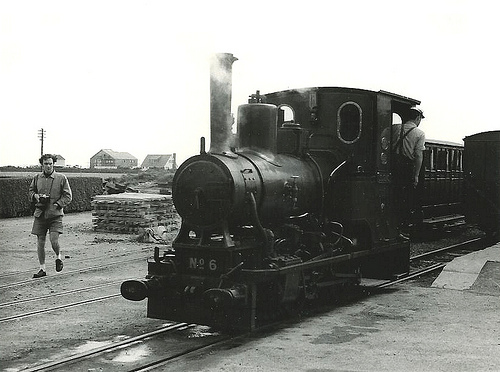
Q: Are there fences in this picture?
A: No, there are no fences.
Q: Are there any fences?
A: No, there are no fences.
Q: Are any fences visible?
A: No, there are no fences.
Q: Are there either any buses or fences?
A: No, there are no fences or buses.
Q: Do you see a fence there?
A: No, there are no fences.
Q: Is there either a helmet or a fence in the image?
A: No, there are no fences or helmets.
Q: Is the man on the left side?
A: Yes, the man is on the left of the image.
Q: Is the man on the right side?
A: No, the man is on the left of the image.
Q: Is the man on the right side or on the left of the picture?
A: The man is on the left of the image.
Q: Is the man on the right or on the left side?
A: The man is on the left of the image.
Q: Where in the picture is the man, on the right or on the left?
A: The man is on the left of the image.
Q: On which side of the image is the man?
A: The man is on the left of the image.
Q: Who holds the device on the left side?
A: The man holds the camera.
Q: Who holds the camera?
A: The man holds the camera.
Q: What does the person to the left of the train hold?
A: The man holds the camera.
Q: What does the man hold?
A: The man holds the camera.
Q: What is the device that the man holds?
A: The device is a camera.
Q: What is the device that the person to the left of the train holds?
A: The device is a camera.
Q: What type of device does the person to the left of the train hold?
A: The man holds the camera.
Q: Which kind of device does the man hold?
A: The man holds the camera.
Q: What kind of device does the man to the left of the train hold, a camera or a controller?
A: The man holds a camera.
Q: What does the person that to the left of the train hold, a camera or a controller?
A: The man holds a camera.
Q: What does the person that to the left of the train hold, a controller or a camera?
A: The man holds a camera.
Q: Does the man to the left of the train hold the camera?
A: Yes, the man holds the camera.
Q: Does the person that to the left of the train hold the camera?
A: Yes, the man holds the camera.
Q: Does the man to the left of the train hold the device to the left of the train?
A: Yes, the man holds the camera.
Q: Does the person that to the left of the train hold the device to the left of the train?
A: Yes, the man holds the camera.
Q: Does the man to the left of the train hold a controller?
A: No, the man holds the camera.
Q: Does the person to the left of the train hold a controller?
A: No, the man holds the camera.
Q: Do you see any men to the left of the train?
A: Yes, there is a man to the left of the train.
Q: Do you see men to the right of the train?
A: No, the man is to the left of the train.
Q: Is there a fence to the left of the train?
A: No, there is a man to the left of the train.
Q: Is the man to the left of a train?
A: Yes, the man is to the left of a train.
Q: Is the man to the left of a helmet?
A: No, the man is to the left of a train.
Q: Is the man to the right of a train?
A: No, the man is to the left of a train.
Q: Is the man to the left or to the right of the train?
A: The man is to the left of the train.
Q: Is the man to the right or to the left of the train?
A: The man is to the left of the train.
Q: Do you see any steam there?
A: Yes, there is steam.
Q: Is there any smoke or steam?
A: Yes, there is steam.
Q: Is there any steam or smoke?
A: Yes, there is steam.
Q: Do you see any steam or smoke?
A: Yes, there is steam.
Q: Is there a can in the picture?
A: No, there are no cans.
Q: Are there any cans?
A: No, there are no cans.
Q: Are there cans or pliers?
A: No, there are no cans or pliers.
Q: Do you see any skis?
A: No, there are no skis.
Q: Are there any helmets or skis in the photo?
A: No, there are no skis or helmets.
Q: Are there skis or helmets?
A: No, there are no skis or helmets.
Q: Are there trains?
A: Yes, there is a train.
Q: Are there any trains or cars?
A: Yes, there is a train.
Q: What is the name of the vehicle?
A: The vehicle is a train.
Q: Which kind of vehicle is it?
A: The vehicle is a train.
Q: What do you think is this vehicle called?
A: This is a train.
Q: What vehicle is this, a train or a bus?
A: This is a train.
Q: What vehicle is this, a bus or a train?
A: This is a train.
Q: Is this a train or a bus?
A: This is a train.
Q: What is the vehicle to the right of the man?
A: The vehicle is a train.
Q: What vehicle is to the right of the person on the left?
A: The vehicle is a train.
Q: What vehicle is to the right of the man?
A: The vehicle is a train.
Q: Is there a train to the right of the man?
A: Yes, there is a train to the right of the man.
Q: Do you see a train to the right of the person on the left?
A: Yes, there is a train to the right of the man.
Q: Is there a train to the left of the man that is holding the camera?
A: No, the train is to the right of the man.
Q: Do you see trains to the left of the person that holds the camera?
A: No, the train is to the right of the man.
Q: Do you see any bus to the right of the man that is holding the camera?
A: No, there is a train to the right of the man.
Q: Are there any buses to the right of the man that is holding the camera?
A: No, there is a train to the right of the man.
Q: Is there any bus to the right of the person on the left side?
A: No, there is a train to the right of the man.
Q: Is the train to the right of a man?
A: Yes, the train is to the right of a man.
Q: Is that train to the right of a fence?
A: No, the train is to the right of a man.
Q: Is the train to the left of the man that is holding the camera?
A: No, the train is to the right of the man.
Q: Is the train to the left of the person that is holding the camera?
A: No, the train is to the right of the man.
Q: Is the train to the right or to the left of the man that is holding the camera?
A: The train is to the right of the man.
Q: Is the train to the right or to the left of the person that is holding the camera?
A: The train is to the right of the man.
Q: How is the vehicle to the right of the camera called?
A: The vehicle is a train.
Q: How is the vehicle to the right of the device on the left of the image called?
A: The vehicle is a train.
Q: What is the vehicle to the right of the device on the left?
A: The vehicle is a train.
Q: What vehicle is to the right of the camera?
A: The vehicle is a train.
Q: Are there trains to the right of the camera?
A: Yes, there is a train to the right of the camera.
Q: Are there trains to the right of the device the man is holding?
A: Yes, there is a train to the right of the camera.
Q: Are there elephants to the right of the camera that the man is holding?
A: No, there is a train to the right of the camera.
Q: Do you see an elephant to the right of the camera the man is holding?
A: No, there is a train to the right of the camera.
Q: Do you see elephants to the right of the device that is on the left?
A: No, there is a train to the right of the camera.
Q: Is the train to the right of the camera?
A: Yes, the train is to the right of the camera.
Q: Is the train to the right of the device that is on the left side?
A: Yes, the train is to the right of the camera.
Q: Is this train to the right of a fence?
A: No, the train is to the right of the camera.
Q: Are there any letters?
A: Yes, there are letters.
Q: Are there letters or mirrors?
A: Yes, there are letters.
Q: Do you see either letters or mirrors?
A: Yes, there are letters.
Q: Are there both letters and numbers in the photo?
A: Yes, there are both letters and numbers.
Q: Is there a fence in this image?
A: No, there are no fences.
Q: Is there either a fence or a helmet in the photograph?
A: No, there are no fences or helmets.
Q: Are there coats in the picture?
A: Yes, there is a coat.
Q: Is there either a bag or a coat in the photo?
A: Yes, there is a coat.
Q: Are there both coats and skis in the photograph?
A: No, there is a coat but no skis.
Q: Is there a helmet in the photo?
A: No, there are no helmets.